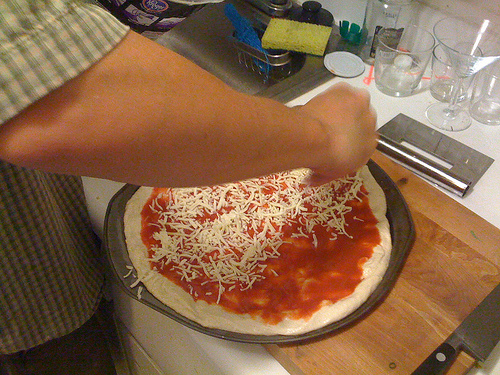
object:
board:
[261, 146, 498, 374]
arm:
[0, 0, 316, 188]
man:
[0, 0, 378, 375]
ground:
[442, 160, 453, 167]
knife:
[410, 284, 499, 374]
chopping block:
[287, 149, 498, 375]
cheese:
[123, 164, 391, 335]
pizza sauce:
[140, 175, 380, 328]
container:
[363, 0, 500, 132]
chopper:
[373, 112, 495, 197]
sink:
[288, 0, 334, 27]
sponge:
[261, 18, 333, 56]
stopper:
[100, 0, 224, 32]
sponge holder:
[229, 0, 295, 81]